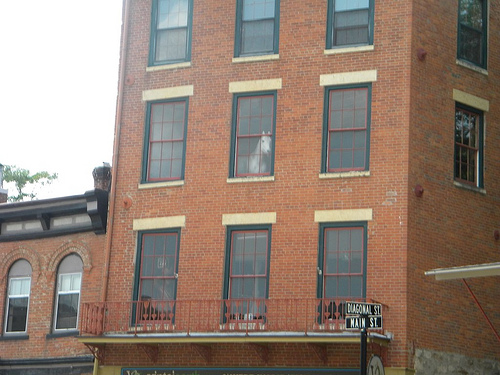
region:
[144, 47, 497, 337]
a rall building in the picture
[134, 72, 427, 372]
the building is mde of bricks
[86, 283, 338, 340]
the building has a balcony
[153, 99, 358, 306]
the building has tall windows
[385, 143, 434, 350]
the wall is brown in color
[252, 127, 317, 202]
the goat is white in color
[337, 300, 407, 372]
a poster is besdie the building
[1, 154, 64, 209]
trees are seen at the edge of the picture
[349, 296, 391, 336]
the words are written in whiye color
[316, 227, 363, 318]
glass window on building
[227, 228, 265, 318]
glass window on building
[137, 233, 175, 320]
glass window on building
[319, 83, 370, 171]
glass window on building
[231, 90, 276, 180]
glass window on building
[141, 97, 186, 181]
glass window on building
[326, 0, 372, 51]
glass window on building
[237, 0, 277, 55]
glass window on building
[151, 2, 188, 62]
glass window on building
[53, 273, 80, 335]
glass window on building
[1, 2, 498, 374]
the large red brick building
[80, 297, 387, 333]
the railing on the building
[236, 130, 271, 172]
the white horse in the window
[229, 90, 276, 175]
the window on the building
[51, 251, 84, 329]
the arched window on the building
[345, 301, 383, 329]
the street signs in front of the building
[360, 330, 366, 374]
the pole for the street signs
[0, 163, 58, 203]
the green leaves on the tree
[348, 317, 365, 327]
the word MAIN on the sign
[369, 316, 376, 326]
the letters "ST" on the sign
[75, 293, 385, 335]
Brown balcony railing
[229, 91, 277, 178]
Dark green trim around windows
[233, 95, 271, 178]
Window with red pane borders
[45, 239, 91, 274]
Arched brick above a window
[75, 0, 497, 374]
Tall brown brick building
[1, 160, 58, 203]
Top of a tree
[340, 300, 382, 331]
Two black and white street signs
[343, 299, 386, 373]
Traffic signs on a pole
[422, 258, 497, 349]
White awning and red rope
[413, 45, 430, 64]
Red fire siren on the side of a building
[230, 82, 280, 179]
A horse looking out a window.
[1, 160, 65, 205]
A tree above the building.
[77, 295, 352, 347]
Red railing in front of the windows.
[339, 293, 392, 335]
Street signs on a pole.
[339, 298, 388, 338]
Black and white signs.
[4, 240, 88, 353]
Two arched windows in the building.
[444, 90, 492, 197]
Window with bars across.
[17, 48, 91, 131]
Pale sky high above.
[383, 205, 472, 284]
Large building made of bricks.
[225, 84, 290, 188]
Photographer wondering why there is a horse in the building.